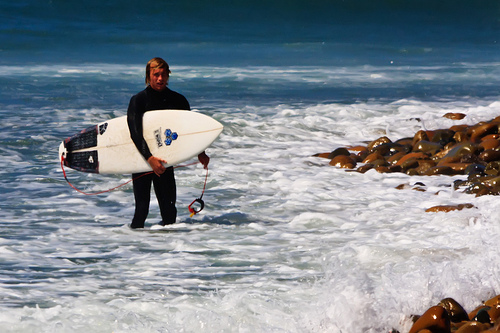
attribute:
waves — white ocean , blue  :
[253, 206, 361, 251]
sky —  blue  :
[3, 1, 496, 45]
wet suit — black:
[125, 82, 209, 230]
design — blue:
[164, 128, 177, 148]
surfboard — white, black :
[56, 109, 223, 174]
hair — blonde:
[138, 57, 177, 86]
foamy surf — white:
[233, 99, 347, 140]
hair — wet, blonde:
[125, 32, 192, 72]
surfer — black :
[127, 57, 212, 229]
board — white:
[58, 104, 230, 177]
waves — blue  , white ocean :
[364, 72, 389, 84]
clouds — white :
[104, 14, 202, 38]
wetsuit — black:
[125, 81, 182, 226]